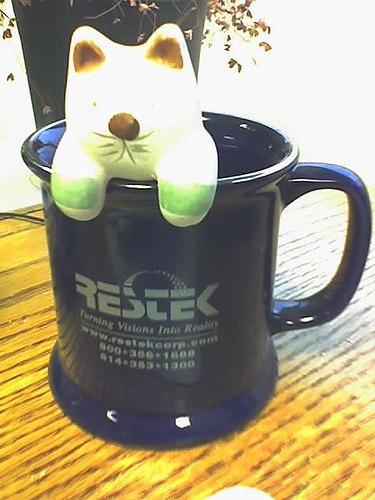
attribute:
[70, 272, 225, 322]
large letters — gray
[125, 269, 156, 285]
lines — curved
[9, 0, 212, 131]
vase — black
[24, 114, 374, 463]
cup — blue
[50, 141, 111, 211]
leg — green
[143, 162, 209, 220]
leg — green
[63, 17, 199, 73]
cat ears — white and brown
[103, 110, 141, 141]
nose — brown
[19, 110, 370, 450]
mug — black, coffee, blue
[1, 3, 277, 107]
leaves — tiny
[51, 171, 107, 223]
paws — green and white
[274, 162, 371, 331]
handle — blue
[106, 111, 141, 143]
nose — oval, brown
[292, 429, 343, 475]
lines — yellow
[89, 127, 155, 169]
whiskers — sideways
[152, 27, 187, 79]
ear — brown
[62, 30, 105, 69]
ear — brown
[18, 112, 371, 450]
coffee mug — black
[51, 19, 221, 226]
cat — ceramic, white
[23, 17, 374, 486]
cup — black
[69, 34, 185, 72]
ears — brown